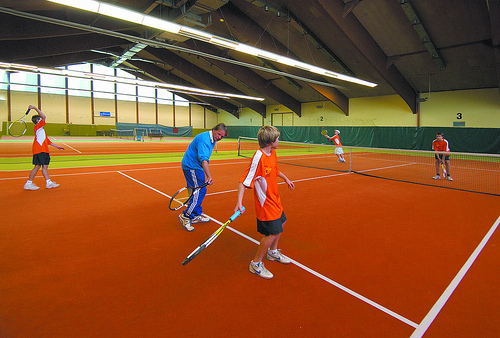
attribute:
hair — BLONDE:
[255, 125, 278, 147]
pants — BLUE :
[181, 167, 206, 219]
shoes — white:
[248, 259, 275, 282]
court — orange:
[177, 128, 494, 317]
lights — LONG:
[1, 2, 381, 101]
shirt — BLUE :
[178, 132, 208, 164]